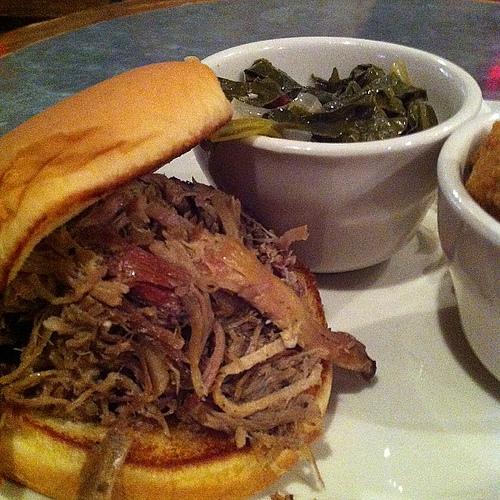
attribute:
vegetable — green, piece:
[233, 55, 435, 127]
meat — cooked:
[0, 170, 377, 498]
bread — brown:
[2, 85, 242, 243]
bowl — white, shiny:
[189, 21, 499, 298]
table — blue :
[1, 0, 499, 137]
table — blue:
[0, 5, 482, 39]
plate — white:
[3, 93, 499, 499]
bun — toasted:
[3, 56, 333, 496]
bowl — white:
[181, 31, 468, 283]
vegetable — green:
[235, 50, 399, 134]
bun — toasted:
[5, 417, 315, 493]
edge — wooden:
[10, 24, 40, 42]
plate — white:
[136, 60, 476, 499]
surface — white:
[388, 373, 472, 487]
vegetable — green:
[233, 57, 427, 135]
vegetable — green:
[221, 59, 462, 144]